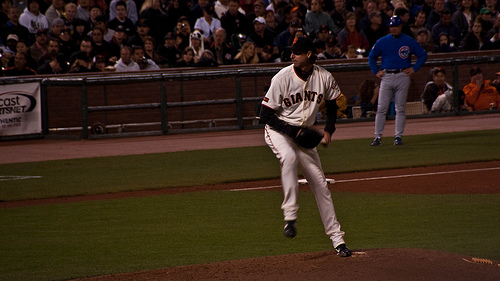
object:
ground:
[1, 113, 500, 281]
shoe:
[335, 243, 352, 258]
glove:
[294, 128, 323, 151]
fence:
[1, 48, 500, 144]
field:
[2, 112, 500, 280]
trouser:
[374, 72, 409, 141]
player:
[258, 35, 353, 257]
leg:
[262, 122, 300, 221]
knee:
[278, 150, 300, 168]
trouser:
[264, 124, 347, 249]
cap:
[286, 36, 319, 55]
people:
[366, 17, 429, 148]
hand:
[404, 67, 414, 75]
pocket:
[399, 72, 412, 84]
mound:
[69, 246, 499, 280]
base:
[295, 176, 337, 186]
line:
[226, 166, 498, 192]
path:
[2, 112, 500, 165]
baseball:
[318, 137, 328, 146]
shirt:
[260, 62, 344, 128]